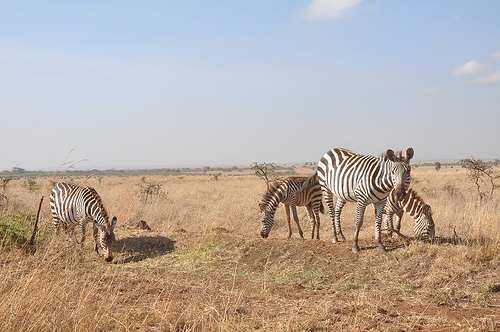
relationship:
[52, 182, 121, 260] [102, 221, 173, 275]
zebra has shadow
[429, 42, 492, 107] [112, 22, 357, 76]
cloud sits in sky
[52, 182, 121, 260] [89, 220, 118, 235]
zebra has ears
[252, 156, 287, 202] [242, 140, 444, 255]
tree behind zebras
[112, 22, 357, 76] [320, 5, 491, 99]
sky has few clouds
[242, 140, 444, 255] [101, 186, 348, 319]
zebras standing in field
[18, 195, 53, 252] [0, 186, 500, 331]
branch sticks up from field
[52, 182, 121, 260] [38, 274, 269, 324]
zebra has head in grass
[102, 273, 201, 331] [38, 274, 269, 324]
dirt part of grass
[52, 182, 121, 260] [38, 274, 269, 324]
zebra eating grass